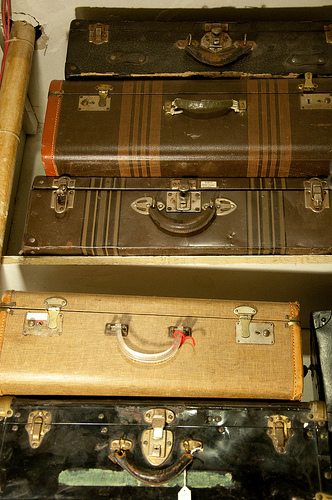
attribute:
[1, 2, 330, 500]
suitcases — grouped, old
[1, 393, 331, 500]
suitcase — black, metal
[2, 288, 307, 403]
suitcase — tan, gold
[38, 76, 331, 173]
suitcase — brown, tan, old, orange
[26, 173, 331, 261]
suitcase — brown, striped, old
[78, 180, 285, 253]
stripes — light brown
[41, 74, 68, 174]
side — orange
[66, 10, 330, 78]
suitcase — dark brown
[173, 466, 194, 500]
tag — white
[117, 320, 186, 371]
handle — clear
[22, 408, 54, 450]
clasp — metal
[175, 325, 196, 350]
ribbon — red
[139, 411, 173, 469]
latch — open